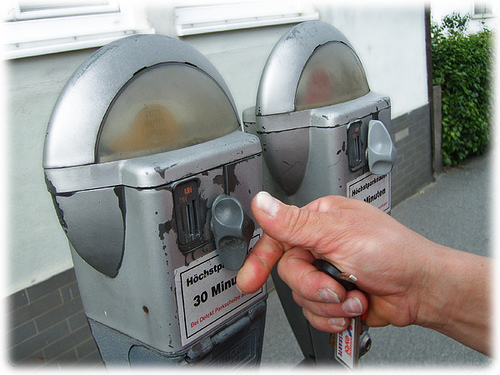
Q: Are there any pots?
A: No, there are no pots.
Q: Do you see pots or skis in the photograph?
A: No, there are no pots or skis.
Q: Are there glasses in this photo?
A: No, there are no glasses.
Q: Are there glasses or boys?
A: No, there are no glasses or boys.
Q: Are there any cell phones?
A: No, there are no cell phones.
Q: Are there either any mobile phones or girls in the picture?
A: No, there are no mobile phones or girls.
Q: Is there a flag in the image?
A: Yes, there is a flag.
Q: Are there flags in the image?
A: Yes, there is a flag.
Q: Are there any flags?
A: Yes, there is a flag.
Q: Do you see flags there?
A: Yes, there is a flag.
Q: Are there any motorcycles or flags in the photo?
A: Yes, there is a flag.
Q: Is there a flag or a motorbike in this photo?
A: Yes, there is a flag.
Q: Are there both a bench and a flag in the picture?
A: No, there is a flag but no benches.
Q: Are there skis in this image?
A: No, there are no skis.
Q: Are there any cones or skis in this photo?
A: No, there are no skis or cones.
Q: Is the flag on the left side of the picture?
A: Yes, the flag is on the left of the image.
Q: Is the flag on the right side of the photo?
A: No, the flag is on the left of the image.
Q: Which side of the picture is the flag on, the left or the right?
A: The flag is on the left of the image.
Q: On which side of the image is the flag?
A: The flag is on the left of the image.